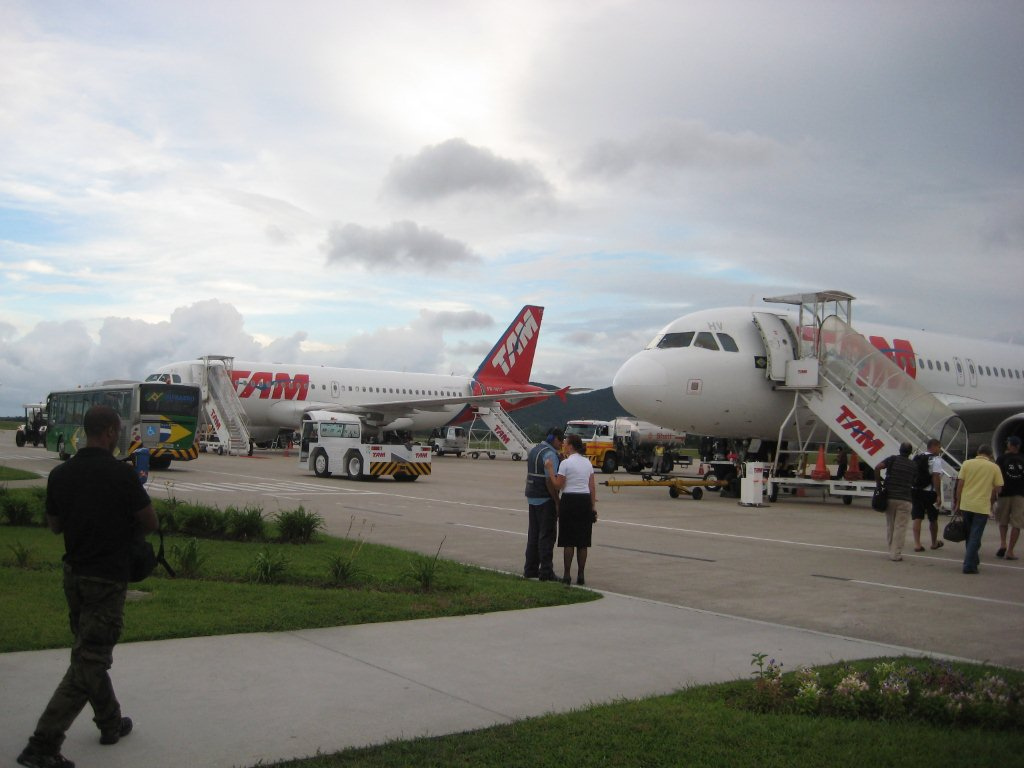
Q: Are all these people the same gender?
A: No, they are both male and female.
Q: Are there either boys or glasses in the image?
A: No, there are no glasses or boys.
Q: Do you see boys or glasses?
A: No, there are no glasses or boys.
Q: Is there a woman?
A: Yes, there is a woman.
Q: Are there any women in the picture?
A: Yes, there is a woman.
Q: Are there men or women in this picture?
A: Yes, there is a woman.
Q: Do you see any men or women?
A: Yes, there is a woman.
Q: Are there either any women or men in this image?
A: Yes, there is a woman.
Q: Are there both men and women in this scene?
A: Yes, there are both a woman and a man.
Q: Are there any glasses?
A: No, there are no glasses.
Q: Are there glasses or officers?
A: No, there are no glasses or officers.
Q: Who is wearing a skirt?
A: The woman is wearing a skirt.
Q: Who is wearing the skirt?
A: The woman is wearing a skirt.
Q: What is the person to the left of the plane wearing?
A: The woman is wearing a skirt.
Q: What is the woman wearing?
A: The woman is wearing a skirt.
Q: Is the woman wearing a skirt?
A: Yes, the woman is wearing a skirt.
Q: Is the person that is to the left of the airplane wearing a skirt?
A: Yes, the woman is wearing a skirt.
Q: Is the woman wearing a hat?
A: No, the woman is wearing a skirt.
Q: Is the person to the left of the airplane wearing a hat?
A: No, the woman is wearing a skirt.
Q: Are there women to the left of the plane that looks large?
A: Yes, there is a woman to the left of the plane.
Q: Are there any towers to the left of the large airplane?
A: No, there is a woman to the left of the plane.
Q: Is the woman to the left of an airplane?
A: Yes, the woman is to the left of an airplane.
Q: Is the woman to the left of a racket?
A: No, the woman is to the left of an airplane.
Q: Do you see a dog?
A: No, there are no dogs.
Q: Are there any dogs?
A: No, there are no dogs.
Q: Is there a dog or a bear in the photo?
A: No, there are no dogs or bears.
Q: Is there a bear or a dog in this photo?
A: No, there are no dogs or bears.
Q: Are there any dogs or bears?
A: No, there are no dogs or bears.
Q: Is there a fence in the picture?
A: No, there are no fences.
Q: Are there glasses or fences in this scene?
A: No, there are no fences or glasses.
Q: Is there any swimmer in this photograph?
A: No, there are no swimmers.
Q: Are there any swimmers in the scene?
A: No, there are no swimmers.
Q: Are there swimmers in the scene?
A: No, there are no swimmers.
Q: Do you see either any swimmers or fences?
A: No, there are no swimmers or fences.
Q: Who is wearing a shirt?
A: The man is wearing a shirt.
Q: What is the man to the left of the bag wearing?
A: The man is wearing a shirt.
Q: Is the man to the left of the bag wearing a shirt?
A: Yes, the man is wearing a shirt.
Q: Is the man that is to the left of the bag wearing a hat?
A: No, the man is wearing a shirt.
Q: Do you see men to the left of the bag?
A: Yes, there is a man to the left of the bag.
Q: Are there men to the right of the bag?
A: No, the man is to the left of the bag.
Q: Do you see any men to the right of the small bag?
A: No, the man is to the left of the bag.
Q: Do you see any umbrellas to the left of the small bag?
A: No, there is a man to the left of the bag.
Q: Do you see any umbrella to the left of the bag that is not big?
A: No, there is a man to the left of the bag.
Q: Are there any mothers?
A: No, there are no mothers.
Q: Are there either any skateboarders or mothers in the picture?
A: No, there are no mothers or skateboarders.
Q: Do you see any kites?
A: No, there are no kites.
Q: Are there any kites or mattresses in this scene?
A: No, there are no kites or mattresses.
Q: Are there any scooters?
A: No, there are no scooters.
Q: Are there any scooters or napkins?
A: No, there are no scooters or napkins.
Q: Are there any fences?
A: No, there are no fences.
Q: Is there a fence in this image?
A: No, there are no fences.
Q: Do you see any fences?
A: No, there are no fences.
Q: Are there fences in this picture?
A: No, there are no fences.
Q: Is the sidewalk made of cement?
A: Yes, the sidewalk is made of cement.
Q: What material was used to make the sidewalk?
A: The sidewalk is made of cement.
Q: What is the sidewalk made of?
A: The sidewalk is made of concrete.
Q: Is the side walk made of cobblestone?
A: No, the side walk is made of cement.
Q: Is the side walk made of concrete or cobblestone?
A: The side walk is made of concrete.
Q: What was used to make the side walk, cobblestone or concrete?
A: The side walk is made of concrete.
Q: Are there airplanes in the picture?
A: Yes, there is an airplane.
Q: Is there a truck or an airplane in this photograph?
A: Yes, there is an airplane.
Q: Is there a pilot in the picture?
A: No, there are no pilots.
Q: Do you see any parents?
A: No, there are no parents.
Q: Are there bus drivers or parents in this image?
A: No, there are no parents or bus drivers.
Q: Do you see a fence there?
A: No, there are no fences.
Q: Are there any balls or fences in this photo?
A: No, there are no fences or balls.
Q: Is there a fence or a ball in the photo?
A: No, there are no fences or balls.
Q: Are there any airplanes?
A: Yes, there is an airplane.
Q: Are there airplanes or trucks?
A: Yes, there is an airplane.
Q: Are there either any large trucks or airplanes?
A: Yes, there is a large airplane.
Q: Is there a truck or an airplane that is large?
A: Yes, the airplane is large.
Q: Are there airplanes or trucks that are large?
A: Yes, the airplane is large.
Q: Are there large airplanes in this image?
A: Yes, there is a large airplane.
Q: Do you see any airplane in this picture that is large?
A: Yes, there is an airplane that is large.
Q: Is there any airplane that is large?
A: Yes, there is an airplane that is large.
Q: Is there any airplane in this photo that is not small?
A: Yes, there is a large airplane.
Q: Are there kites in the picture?
A: No, there are no kites.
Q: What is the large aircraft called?
A: The aircraft is an airplane.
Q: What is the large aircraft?
A: The aircraft is an airplane.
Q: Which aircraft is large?
A: The aircraft is an airplane.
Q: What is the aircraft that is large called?
A: The aircraft is an airplane.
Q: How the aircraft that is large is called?
A: The aircraft is an airplane.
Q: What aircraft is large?
A: The aircraft is an airplane.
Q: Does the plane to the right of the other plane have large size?
A: Yes, the plane is large.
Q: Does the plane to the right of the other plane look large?
A: Yes, the plane is large.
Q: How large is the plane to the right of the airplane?
A: The airplane is large.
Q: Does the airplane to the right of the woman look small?
A: No, the airplane is large.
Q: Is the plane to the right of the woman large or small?
A: The plane is large.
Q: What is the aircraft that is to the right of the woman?
A: The aircraft is an airplane.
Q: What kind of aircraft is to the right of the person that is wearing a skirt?
A: The aircraft is an airplane.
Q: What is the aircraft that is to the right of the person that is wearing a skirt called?
A: The aircraft is an airplane.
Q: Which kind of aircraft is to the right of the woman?
A: The aircraft is an airplane.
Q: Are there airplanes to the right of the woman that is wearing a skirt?
A: Yes, there is an airplane to the right of the woman.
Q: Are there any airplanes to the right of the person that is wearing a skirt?
A: Yes, there is an airplane to the right of the woman.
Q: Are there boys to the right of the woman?
A: No, there is an airplane to the right of the woman.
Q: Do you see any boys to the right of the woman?
A: No, there is an airplane to the right of the woman.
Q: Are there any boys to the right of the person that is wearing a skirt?
A: No, there is an airplane to the right of the woman.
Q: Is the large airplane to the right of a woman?
A: Yes, the airplane is to the right of a woman.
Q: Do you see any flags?
A: No, there are no flags.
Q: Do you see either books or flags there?
A: No, there are no flags or books.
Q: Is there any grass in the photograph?
A: Yes, there is grass.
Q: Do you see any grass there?
A: Yes, there is grass.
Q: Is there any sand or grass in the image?
A: Yes, there is grass.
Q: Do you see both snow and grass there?
A: No, there is grass but no snow.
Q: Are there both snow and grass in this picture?
A: No, there is grass but no snow.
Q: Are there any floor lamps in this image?
A: No, there are no floor lamps.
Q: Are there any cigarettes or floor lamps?
A: No, there are no floor lamps or cigarettes.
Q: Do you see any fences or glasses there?
A: No, there are no fences or glasses.